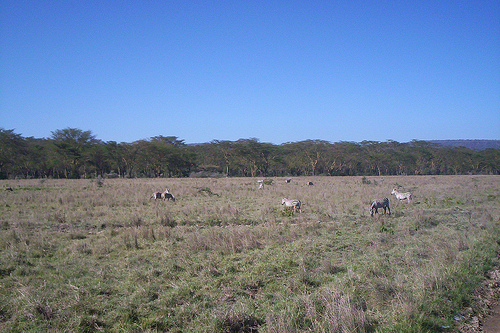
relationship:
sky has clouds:
[155, 56, 330, 103] [385, 47, 418, 95]